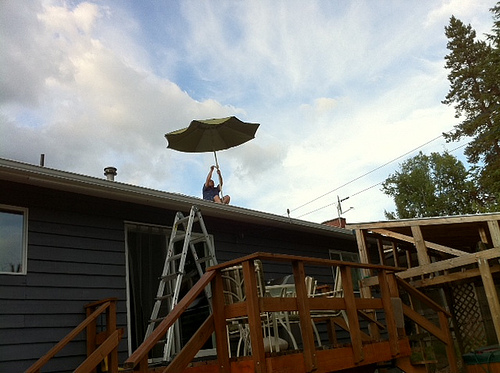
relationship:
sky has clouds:
[4, 0, 497, 228] [23, 20, 175, 165]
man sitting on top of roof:
[202, 162, 231, 205] [3, 158, 353, 239]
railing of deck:
[190, 236, 426, 367] [87, 272, 301, 366]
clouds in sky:
[346, 64, 426, 139] [143, 22, 274, 134]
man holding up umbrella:
[202, 162, 231, 205] [168, 115, 269, 155]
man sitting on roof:
[194, 162, 231, 204] [3, 144, 363, 239]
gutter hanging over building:
[22, 149, 164, 207] [35, 159, 395, 336]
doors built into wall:
[118, 215, 225, 371] [1, 157, 426, 372]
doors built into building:
[118, 215, 225, 371] [0, 157, 500, 373]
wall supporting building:
[1, 157, 426, 372] [0, 157, 500, 373]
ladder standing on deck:
[144, 205, 216, 362] [22, 250, 460, 372]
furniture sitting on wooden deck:
[219, 259, 351, 360] [84, 252, 410, 371]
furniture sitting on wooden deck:
[263, 270, 324, 350] [84, 252, 410, 371]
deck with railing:
[22, 250, 460, 372] [207, 252, 408, 372]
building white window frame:
[0, 157, 500, 373] [0, 203, 29, 274]